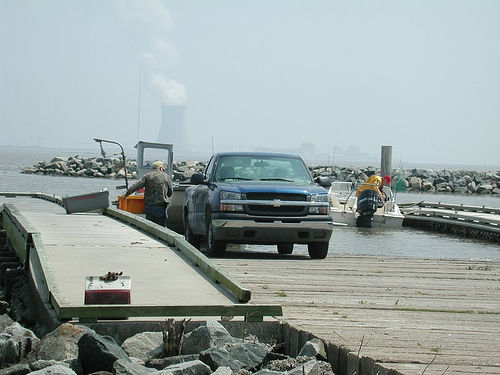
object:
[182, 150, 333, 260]
pick-up truck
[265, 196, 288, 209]
logo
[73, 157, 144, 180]
jetty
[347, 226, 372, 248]
water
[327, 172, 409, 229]
boat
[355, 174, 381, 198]
rain coat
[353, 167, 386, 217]
peson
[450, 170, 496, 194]
rocks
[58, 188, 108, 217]
container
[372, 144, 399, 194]
pole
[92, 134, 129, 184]
pole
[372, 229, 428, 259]
water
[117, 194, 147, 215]
container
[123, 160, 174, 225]
man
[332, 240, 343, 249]
water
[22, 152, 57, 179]
rocks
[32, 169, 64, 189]
water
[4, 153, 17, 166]
water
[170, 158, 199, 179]
rocks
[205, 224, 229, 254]
wheel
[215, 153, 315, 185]
windshield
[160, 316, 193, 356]
tree stump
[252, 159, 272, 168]
mirror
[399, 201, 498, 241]
dock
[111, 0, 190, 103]
smoke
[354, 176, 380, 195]
coat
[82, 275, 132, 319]
box